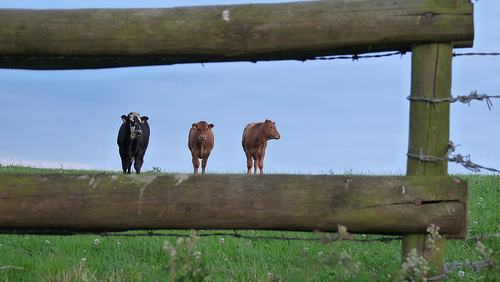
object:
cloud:
[0, 156, 94, 170]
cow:
[241, 118, 280, 175]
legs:
[131, 153, 143, 175]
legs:
[244, 155, 252, 175]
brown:
[240, 119, 281, 175]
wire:
[449, 52, 498, 57]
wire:
[403, 90, 498, 110]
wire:
[404, 142, 499, 173]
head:
[258, 118, 281, 140]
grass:
[0, 160, 499, 281]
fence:
[0, 0, 499, 281]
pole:
[397, 43, 454, 282]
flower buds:
[428, 222, 436, 229]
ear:
[189, 123, 198, 127]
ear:
[207, 123, 215, 130]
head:
[189, 121, 215, 141]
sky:
[0, 0, 499, 175]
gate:
[0, 0, 499, 281]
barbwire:
[404, 257, 499, 281]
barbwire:
[445, 233, 498, 242]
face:
[126, 114, 143, 138]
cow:
[116, 111, 151, 175]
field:
[0, 163, 499, 282]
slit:
[391, 197, 460, 206]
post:
[0, 171, 468, 236]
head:
[118, 112, 150, 140]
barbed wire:
[198, 49, 412, 68]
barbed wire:
[93, 229, 407, 245]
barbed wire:
[448, 51, 500, 58]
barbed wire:
[404, 89, 498, 110]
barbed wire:
[404, 139, 500, 173]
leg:
[199, 154, 209, 175]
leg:
[190, 154, 198, 174]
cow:
[186, 120, 215, 175]